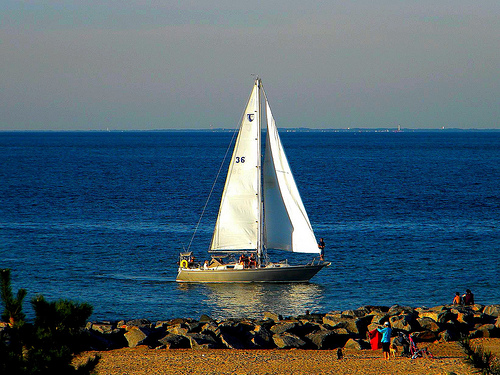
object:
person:
[372, 319, 394, 361]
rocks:
[271, 332, 306, 349]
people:
[462, 289, 475, 305]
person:
[317, 238, 324, 260]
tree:
[0, 266, 90, 375]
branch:
[14, 287, 30, 307]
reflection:
[0, 214, 206, 239]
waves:
[0, 132, 500, 328]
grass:
[449, 337, 500, 375]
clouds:
[0, 0, 500, 133]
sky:
[0, 0, 500, 132]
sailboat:
[178, 71, 333, 283]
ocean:
[0, 129, 500, 324]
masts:
[211, 77, 260, 252]